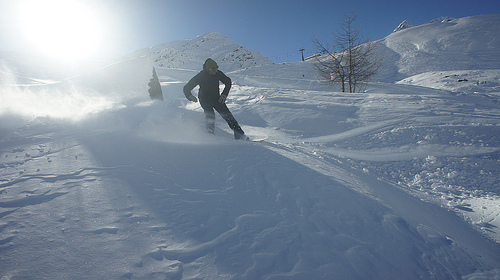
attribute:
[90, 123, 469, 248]
snow — white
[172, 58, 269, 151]
man — snowboarding, white, boarding, skiing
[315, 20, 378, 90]
trees — bare, dead, brown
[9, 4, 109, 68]
sun — yellow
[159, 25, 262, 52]
mountain — white, tall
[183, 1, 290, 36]
sky — blue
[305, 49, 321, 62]
building — red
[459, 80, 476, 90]
rocks — black